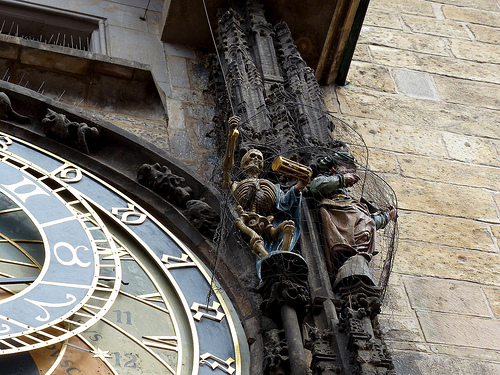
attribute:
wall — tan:
[77, 2, 187, 83]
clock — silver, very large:
[3, 125, 257, 373]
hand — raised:
[227, 114, 247, 146]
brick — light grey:
[389, 63, 441, 101]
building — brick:
[0, 0, 499, 372]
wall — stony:
[334, 39, 471, 278]